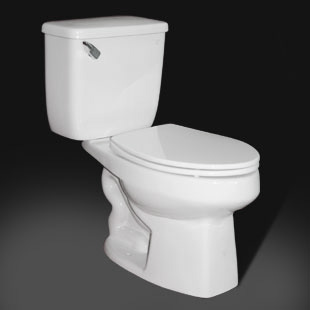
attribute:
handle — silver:
[84, 40, 99, 59]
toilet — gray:
[38, 32, 261, 285]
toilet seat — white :
[106, 120, 261, 178]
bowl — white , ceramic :
[100, 84, 235, 197]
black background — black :
[2, 2, 306, 169]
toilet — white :
[46, 10, 250, 268]